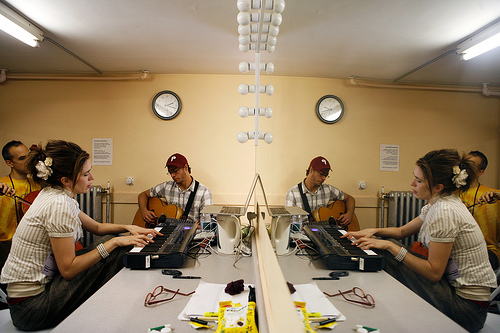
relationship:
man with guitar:
[145, 143, 199, 194] [128, 192, 197, 234]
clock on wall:
[147, 88, 189, 128] [106, 73, 223, 154]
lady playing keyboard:
[16, 128, 102, 205] [122, 201, 195, 283]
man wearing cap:
[145, 143, 199, 194] [161, 153, 196, 174]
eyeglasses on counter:
[143, 285, 182, 309] [105, 254, 184, 324]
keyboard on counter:
[122, 201, 195, 283] [105, 254, 184, 324]